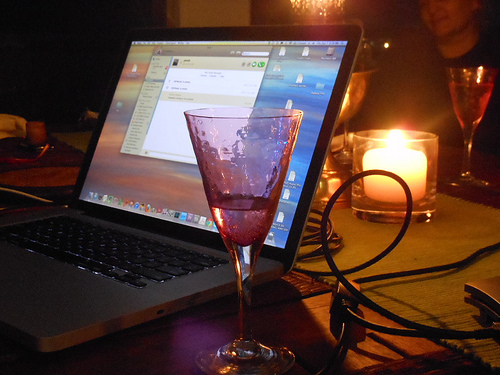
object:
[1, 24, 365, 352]
laptop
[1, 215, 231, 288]
keyboard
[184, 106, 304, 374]
glass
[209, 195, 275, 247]
liquid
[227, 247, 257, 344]
stem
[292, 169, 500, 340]
cord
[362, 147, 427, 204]
candle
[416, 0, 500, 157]
person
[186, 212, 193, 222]
icons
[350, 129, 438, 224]
glass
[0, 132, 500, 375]
table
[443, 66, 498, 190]
glass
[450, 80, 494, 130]
wine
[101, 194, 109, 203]
icon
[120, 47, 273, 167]
window